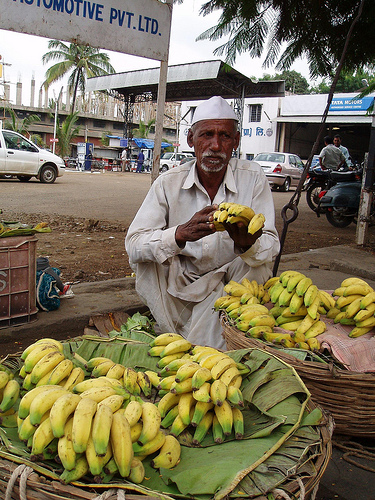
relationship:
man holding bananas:
[124, 94, 280, 352] [210, 198, 268, 240]